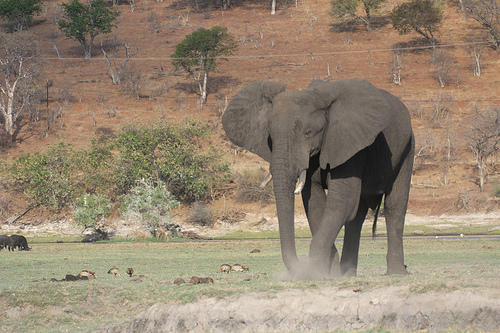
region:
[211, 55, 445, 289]
Elephant walking in field.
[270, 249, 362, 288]
Dust rising around elephant's feet.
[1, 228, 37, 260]
Water buffalo grazing in field.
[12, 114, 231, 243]
Scrub bush growing on side of hill.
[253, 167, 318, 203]
Elephant's two short tusk.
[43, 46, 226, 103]
Fence surrounding field with animals.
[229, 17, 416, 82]
Brown grass growing on hill side.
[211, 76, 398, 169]
Elephant's two large ears.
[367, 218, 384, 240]
Tip of elephant's tail.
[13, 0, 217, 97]
Trees growing on side of hill.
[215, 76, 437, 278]
an elephant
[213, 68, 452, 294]
a large elephant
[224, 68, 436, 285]
an adult elephant in a field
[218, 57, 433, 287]
the elephant is walking in the dirt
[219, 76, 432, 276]
the elephant has tusks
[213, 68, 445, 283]
the elephant has large ears that are erect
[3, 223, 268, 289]
other animals are in the field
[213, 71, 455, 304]
dust is stirred up as the elephant walks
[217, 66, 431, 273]
the elephant has it's trunk down to the ground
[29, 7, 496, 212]
brush is on the hill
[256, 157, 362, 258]
Ivory tusks on elephant.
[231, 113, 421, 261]
Elephant is gray in color.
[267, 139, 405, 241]
Elephant is walking in field.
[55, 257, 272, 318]
Animals laying down in the background.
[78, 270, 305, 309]
Animals laying down are brown in color.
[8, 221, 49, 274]
Animals bending down eating.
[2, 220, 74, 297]
Animals eating are black.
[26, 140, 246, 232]
Large green tree on hillside.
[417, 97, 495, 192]
Trees on the right have no leaves.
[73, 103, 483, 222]
Large dirt hillside in the background.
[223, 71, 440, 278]
the elephant walking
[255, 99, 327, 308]
the elephants trunk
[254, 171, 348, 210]
the tusks of the walking elephant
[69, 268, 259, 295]
the animals on the ground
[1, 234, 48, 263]
the rhinos in the background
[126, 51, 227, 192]
the trees on the hill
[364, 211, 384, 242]
the tail of the elephant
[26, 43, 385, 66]
the powercord that is behind the elephant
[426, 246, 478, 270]
the grass the elephant is walking on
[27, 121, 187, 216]
the pile of bushes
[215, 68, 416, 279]
Elephant walking in a prairie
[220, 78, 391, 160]
Big ears of elephant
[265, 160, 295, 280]
Trunk elephant touching the soil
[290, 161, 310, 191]
Elephant task over mouth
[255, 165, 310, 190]
Two elephant tusks above mouth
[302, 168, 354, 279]
Front legs of elephant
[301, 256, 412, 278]
Four foot of elephant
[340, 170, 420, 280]
Back legs of elephant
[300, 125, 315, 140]
Left eye of elephant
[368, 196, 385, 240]
Long tail of elephant